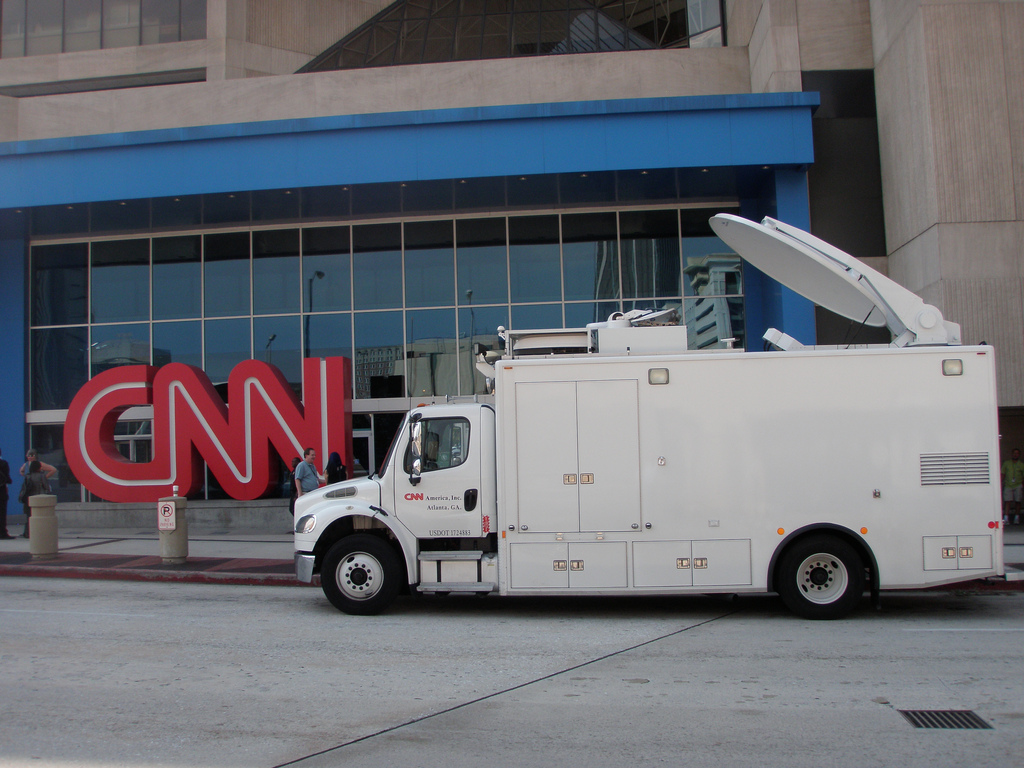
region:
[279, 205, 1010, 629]
White truck in front of the building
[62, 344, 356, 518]
Red and white lettering on the building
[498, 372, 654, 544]
Doors on the truck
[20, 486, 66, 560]
Cement pillar on the pavement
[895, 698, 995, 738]
Drain in the street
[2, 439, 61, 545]
People on the pavement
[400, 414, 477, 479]
Window in the truck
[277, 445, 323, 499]
Man in a blue shirt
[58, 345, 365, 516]
A red sign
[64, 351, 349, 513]
The red sign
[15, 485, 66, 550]
A stone post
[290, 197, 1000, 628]
A white news truck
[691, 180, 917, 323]
A white satellite dish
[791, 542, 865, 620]
The rear tire of the news van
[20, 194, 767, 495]
The glass windows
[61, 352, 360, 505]
Cable T.V. sign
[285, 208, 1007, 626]
white news van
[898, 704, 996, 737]
ground grate on street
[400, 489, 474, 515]
cable news sticker on van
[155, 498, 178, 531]
parking sign on post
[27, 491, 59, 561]
small post on sidewalk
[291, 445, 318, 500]
Man standing outside of building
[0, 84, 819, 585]
Blue area of a building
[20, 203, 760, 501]
Glass panes of a building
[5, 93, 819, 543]
Entrance of cable news building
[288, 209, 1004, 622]
White CNN satellite truck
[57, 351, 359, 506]
Larger than life CNN sign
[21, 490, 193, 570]
Concrete posts outside entrance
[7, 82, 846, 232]
Blue awning over entrance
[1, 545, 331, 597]
Street curb painted red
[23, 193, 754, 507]
Glass wall at front entrance of CNN Center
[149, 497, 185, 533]
No Parking sign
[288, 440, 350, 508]
A couple people standing around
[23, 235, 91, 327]
glass window pane on CNN building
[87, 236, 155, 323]
glass window pane on CNN building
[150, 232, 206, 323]
glass window pane on CNN building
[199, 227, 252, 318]
glass window pane on CNN building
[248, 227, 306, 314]
glass window pane on CNN building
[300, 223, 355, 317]
glass window pane on CNN building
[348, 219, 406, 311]
glass window pane on CNN building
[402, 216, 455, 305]
glass window pane on CNN building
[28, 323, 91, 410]
glass window pane on CNN building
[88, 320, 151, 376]
glass window pane on CNN building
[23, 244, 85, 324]
a window on a building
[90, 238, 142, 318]
a window on a building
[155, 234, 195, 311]
a window on a building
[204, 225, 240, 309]
a window on a building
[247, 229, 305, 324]
a window on a building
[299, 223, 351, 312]
a window on a building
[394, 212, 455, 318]
a window on a building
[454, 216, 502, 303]
a window on a building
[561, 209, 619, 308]
a window on a building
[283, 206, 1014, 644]
White truck parked near building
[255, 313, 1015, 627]
White truck parked on street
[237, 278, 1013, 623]
White truck parked on road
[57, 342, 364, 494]
Large sign on building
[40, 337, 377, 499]
Red sign on building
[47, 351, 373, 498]
Red and white sign on building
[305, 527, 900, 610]
Black tires on truck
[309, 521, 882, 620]
Black tires on white truck